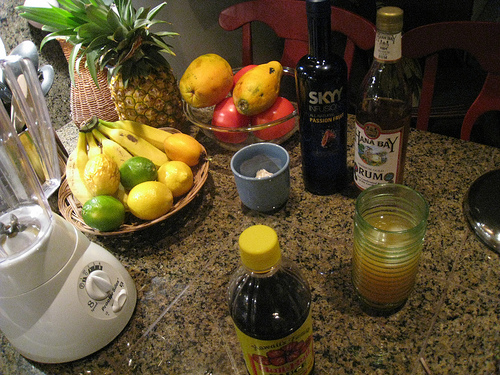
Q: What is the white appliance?
A: A blender.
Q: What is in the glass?
A: Orange juice.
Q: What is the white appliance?
A: Blender.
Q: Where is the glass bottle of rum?
A: On table.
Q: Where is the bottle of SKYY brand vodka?
A: Next to the bottle of rum.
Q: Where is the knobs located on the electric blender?
A: On the front.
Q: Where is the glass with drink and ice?
A: On table.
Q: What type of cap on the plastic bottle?
A: Plastic cap.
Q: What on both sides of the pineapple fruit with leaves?
A: Bunch of fruits.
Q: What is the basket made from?
A: Brown straw.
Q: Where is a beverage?
A: In a glass.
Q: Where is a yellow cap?
A: On the bottle.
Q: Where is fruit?
A: In a bowl.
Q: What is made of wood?
A: The chairs.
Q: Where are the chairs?
A: Next to the table.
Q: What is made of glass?
A: Fruit bowl.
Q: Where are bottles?
A: On the table.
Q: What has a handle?
A: Blender.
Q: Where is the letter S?
A: On the bottle.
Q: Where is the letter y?
A: On the bottle.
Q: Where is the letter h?
A: On the bottle.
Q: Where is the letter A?
A: On the bottle.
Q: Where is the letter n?
A: On the bottle.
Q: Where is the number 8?
A: On the blender.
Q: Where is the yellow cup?
A: On the bottle.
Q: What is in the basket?
A: Fruit.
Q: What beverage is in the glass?
A: Orange juice.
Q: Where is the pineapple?
A: Behind the bowl.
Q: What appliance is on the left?
A: Blender.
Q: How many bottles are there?
A: 2.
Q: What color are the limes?
A: Green.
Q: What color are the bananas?
A: Yellow.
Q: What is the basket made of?
A: Wicker.